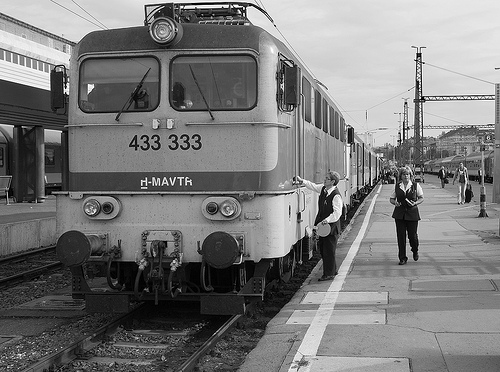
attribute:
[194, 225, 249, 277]
ram — safety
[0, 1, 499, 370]
photo — black, white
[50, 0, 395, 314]
train — parked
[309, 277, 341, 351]
line — white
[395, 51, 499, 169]
frame — black, metal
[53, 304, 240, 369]
track — black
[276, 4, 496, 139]
sky — grey, cloudy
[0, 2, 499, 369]
picture — black and white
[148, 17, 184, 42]
light — white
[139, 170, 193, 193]
writing — white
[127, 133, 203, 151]
numbers — black